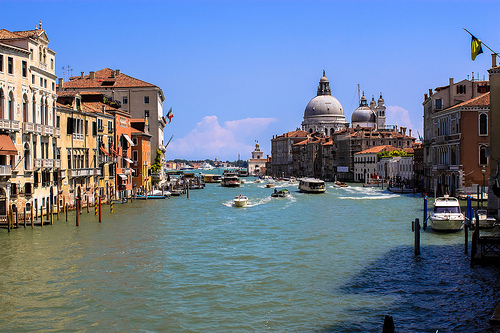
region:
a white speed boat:
[232, 191, 250, 208]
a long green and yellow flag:
[458, 26, 498, 62]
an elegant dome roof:
[303, 68, 345, 124]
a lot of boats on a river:
[171, 159, 339, 229]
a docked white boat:
[426, 192, 463, 232]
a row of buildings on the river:
[0, 23, 167, 218]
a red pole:
[71, 195, 84, 226]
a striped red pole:
[108, 180, 115, 210]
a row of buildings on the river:
[271, 69, 419, 176]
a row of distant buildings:
[161, 158, 242, 170]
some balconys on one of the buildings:
[21, 116, 63, 141]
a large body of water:
[153, 249, 289, 301]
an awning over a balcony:
[1, 132, 24, 157]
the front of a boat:
[426, 213, 471, 235]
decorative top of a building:
[292, 65, 409, 125]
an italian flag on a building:
[161, 105, 181, 125]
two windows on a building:
[471, 112, 493, 170]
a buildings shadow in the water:
[350, 233, 430, 320]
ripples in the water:
[186, 248, 234, 294]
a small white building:
[353, 148, 413, 183]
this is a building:
[0, 26, 66, 216]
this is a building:
[59, 80, 140, 222]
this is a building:
[71, 58, 178, 186]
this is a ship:
[229, 178, 262, 232]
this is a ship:
[274, 163, 323, 218]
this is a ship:
[207, 159, 244, 197]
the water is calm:
[126, 263, 191, 321]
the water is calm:
[224, 235, 273, 294]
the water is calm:
[84, 232, 166, 316]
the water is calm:
[304, 239, 389, 308]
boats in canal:
[227, 163, 325, 217]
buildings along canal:
[11, 49, 163, 210]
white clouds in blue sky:
[217, 122, 237, 146]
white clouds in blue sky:
[178, 51, 219, 95]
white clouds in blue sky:
[221, 66, 266, 106]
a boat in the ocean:
[292, 175, 329, 199]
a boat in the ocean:
[219, 170, 242, 190]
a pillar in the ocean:
[405, 215, 427, 266]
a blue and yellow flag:
[459, 25, 486, 69]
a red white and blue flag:
[160, 105, 175, 125]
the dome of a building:
[301, 68, 346, 125]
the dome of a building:
[350, 90, 375, 130]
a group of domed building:
[295, 70, 380, 140]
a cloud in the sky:
[179, 113, 275, 160]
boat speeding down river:
[232, 193, 249, 207]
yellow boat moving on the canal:
[233, 192, 247, 206]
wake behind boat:
[245, 193, 271, 206]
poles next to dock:
[3, 196, 53, 228]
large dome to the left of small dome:
[296, 66, 373, 131]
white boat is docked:
[425, 195, 465, 230]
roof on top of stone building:
[55, 65, 165, 185]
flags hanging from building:
[157, 105, 172, 130]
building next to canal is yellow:
[55, 90, 100, 210]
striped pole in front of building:
[107, 180, 109, 211]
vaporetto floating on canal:
[298, 175, 326, 193]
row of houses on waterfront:
[1, 16, 173, 230]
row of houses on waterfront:
[0, 8, 189, 227]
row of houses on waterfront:
[1, 15, 190, 240]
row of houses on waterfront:
[3, 29, 188, 241]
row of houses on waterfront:
[4, 13, 189, 230]